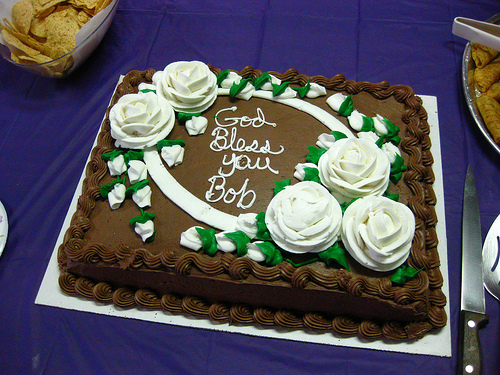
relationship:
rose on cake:
[260, 177, 341, 256] [47, 57, 445, 346]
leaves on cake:
[227, 229, 274, 263] [47, 57, 445, 346]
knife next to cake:
[450, 155, 492, 373] [47, 57, 445, 346]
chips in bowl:
[9, 7, 93, 67] [2, 4, 111, 83]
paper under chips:
[8, 5, 108, 62] [5, 4, 86, 71]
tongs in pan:
[448, 16, 498, 50] [456, 14, 499, 160]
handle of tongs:
[450, 15, 497, 51] [450, 13, 498, 61]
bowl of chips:
[4, 3, 115, 75] [2, 4, 108, 63]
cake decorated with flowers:
[47, 57, 445, 346] [260, 125, 418, 277]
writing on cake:
[202, 104, 284, 211] [34, 49, 460, 344]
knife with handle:
[450, 155, 492, 373] [454, 308, 495, 373]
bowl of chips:
[4, 3, 115, 75] [6, 2, 76, 67]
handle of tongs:
[450, 15, 497, 51] [444, 5, 497, 43]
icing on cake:
[59, 235, 206, 316] [47, 57, 445, 346]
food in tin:
[455, 15, 498, 144] [448, 25, 498, 161]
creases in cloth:
[246, 17, 379, 68] [3, 2, 495, 372]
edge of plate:
[1, 193, 20, 267] [0, 196, 12, 268]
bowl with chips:
[4, 3, 115, 75] [11, 5, 66, 60]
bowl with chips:
[4, 3, 115, 75] [4, 3, 74, 62]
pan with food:
[456, 14, 499, 160] [472, 45, 497, 133]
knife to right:
[450, 155, 492, 373] [334, 29, 487, 372]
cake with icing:
[47, 51, 446, 360] [91, 60, 417, 295]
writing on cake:
[193, 94, 290, 213] [47, 51, 446, 360]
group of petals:
[270, 125, 425, 291] [266, 125, 417, 292]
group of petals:
[108, 54, 232, 154] [107, 59, 217, 149]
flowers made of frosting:
[261, 126, 427, 292] [262, 133, 428, 278]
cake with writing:
[47, 51, 446, 360] [206, 96, 293, 225]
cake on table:
[47, 57, 445, 346] [1, 3, 489, 373]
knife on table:
[450, 155, 492, 373] [1, 3, 489, 373]